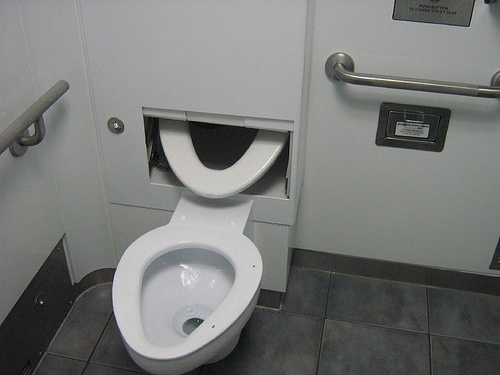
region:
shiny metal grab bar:
[326, 51, 498, 101]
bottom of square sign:
[392, 0, 474, 26]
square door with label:
[372, 101, 452, 153]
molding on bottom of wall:
[294, 244, 499, 296]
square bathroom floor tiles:
[32, 262, 497, 374]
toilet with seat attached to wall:
[110, 195, 261, 372]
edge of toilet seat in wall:
[151, 119, 279, 200]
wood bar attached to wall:
[0, 77, 70, 163]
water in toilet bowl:
[172, 300, 212, 338]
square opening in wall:
[139, 106, 294, 201]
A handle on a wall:
[327, 60, 497, 115]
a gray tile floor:
[308, 280, 430, 361]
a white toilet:
[85, 205, 282, 365]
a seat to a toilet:
[147, 100, 288, 212]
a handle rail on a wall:
[14, 63, 81, 177]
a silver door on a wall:
[372, 100, 460, 163]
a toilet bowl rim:
[110, 233, 155, 350]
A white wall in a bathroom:
[324, 173, 473, 278]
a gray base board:
[317, 255, 458, 287]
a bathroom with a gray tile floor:
[25, 69, 495, 366]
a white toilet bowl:
[110, 198, 260, 373]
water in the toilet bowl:
[170, 302, 212, 335]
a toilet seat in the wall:
[158, 133, 284, 198]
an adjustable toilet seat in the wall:
[140, 107, 292, 199]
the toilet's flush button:
[106, 115, 125, 135]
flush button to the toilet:
[105, 117, 125, 134]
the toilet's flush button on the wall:
[107, 117, 124, 134]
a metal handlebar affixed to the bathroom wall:
[1, 80, 70, 157]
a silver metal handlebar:
[323, 52, 498, 99]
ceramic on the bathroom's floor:
[285, 293, 499, 373]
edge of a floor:
[377, 294, 396, 304]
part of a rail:
[385, 80, 391, 87]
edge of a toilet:
[223, 177, 235, 182]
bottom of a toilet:
[233, 333, 243, 344]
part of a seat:
[210, 188, 218, 203]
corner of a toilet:
[280, 265, 287, 297]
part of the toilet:
[236, 300, 239, 317]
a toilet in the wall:
[110, 113, 290, 373]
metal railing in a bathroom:
[1, 81, 68, 186]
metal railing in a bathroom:
[327, 58, 498, 103]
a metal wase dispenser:
[376, 103, 448, 155]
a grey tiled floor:
[38, 268, 498, 374]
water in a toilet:
[166, 301, 214, 336]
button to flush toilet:
[105, 116, 122, 134]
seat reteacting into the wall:
[141, 105, 286, 201]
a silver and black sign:
[392, 0, 473, 25]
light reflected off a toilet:
[175, 261, 225, 290]